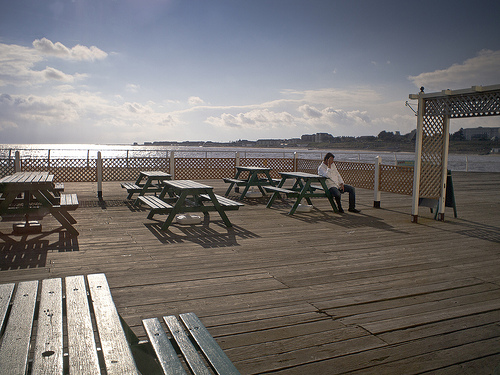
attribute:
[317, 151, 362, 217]
person — light skinned, alone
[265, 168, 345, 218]
picnic table — wooden, green, wood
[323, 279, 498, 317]
plank — brown, wooden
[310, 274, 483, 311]
plank — brown, wooden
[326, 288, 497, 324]
plank — brown, wooden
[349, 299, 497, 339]
plank — brown, wooden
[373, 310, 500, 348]
plank — brown, wooden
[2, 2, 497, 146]
sky — blue, clear, cloud filled, partly cloudy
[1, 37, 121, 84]
cloud — white, fluffy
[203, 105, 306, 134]
cloud — white, fluffy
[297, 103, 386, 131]
cloud — white, fluffy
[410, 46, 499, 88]
cloud — white, fluffy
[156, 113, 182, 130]
cloud — white, fluffy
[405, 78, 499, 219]
trellis — upright, brown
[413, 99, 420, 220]
support pole — white, wooden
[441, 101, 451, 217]
support pole — white, wooden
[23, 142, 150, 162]
reflection — bright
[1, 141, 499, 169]
water — blue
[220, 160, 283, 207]
picnic table — wooden, green, wood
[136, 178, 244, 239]
picnic table — wooden, green, wood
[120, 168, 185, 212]
picnic table — wooden, green, wood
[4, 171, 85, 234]
picnic table — wooden, green, wood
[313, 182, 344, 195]
bench — wooden, green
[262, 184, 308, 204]
bench — wooden, green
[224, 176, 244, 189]
bench — wooden, green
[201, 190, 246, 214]
bench — wooden, green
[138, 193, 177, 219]
bench — wooden, green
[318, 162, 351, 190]
shirt — white, long sleeved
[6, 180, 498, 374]
flooring — wood, plank